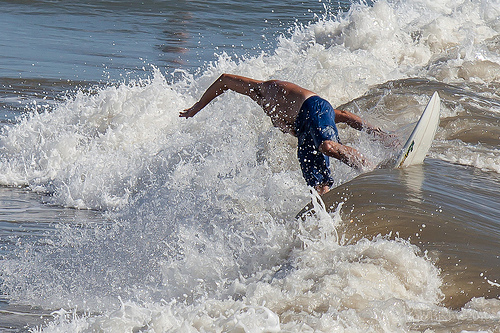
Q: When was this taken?
A: Day time.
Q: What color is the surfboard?
A: White.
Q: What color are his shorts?
A: Blue.